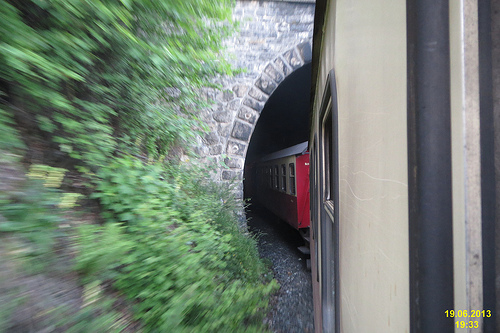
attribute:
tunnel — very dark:
[234, 43, 313, 284]